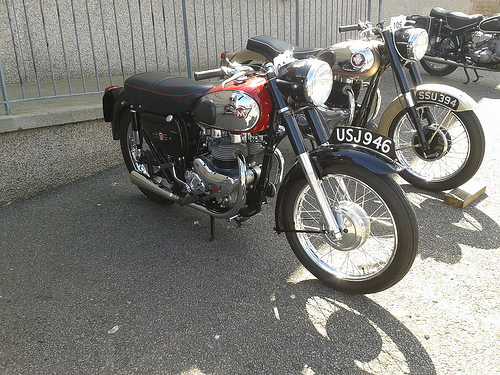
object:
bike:
[101, 33, 419, 295]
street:
[1, 60, 500, 374]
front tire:
[279, 158, 420, 294]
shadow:
[0, 59, 499, 373]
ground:
[1, 60, 499, 374]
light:
[426, 264, 499, 375]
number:
[362, 131, 373, 146]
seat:
[122, 69, 215, 116]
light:
[285, 56, 335, 108]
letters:
[336, 128, 346, 142]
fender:
[274, 143, 402, 235]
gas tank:
[191, 76, 275, 134]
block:
[443, 179, 489, 210]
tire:
[388, 100, 486, 192]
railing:
[0, 0, 372, 117]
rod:
[22, 0, 42, 97]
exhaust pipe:
[130, 170, 179, 201]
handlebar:
[192, 57, 264, 89]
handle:
[193, 67, 224, 81]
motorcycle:
[218, 15, 486, 192]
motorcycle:
[411, 7, 500, 85]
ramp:
[0, 70, 222, 209]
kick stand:
[208, 215, 217, 242]